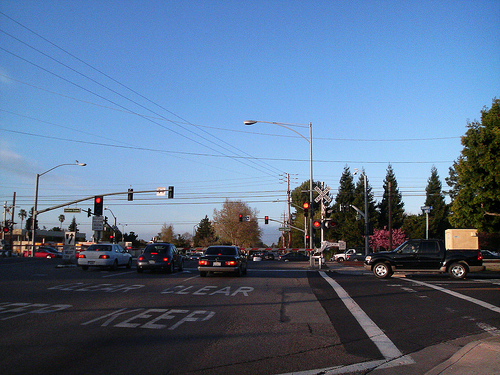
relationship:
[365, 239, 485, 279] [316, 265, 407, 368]
pickup truck at crosswalk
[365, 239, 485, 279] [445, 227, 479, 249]
pickup truck with container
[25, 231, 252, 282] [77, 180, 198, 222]
cars stopped at light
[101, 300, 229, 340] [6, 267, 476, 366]
word keep painted on street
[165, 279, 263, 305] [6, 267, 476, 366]
word clear painted on street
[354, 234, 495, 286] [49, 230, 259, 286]
pickup truck negotiating traffic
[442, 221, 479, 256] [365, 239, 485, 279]
container in back of pickup truck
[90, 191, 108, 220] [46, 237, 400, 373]
traffic signal at intersection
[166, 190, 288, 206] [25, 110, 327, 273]
power wires strung between utility poles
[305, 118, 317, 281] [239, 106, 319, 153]
support pole for streetlight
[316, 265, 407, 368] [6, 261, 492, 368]
crosswalk painted on street